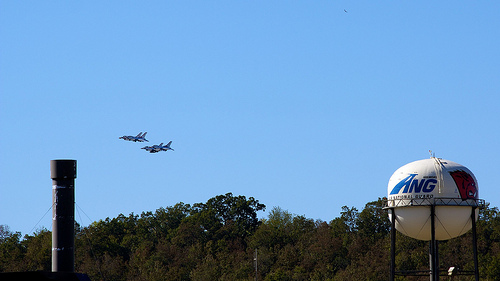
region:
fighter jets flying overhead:
[118, 115, 198, 169]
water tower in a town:
[394, 151, 464, 277]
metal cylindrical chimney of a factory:
[29, 146, 95, 279]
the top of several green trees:
[143, 206, 359, 271]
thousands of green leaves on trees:
[117, 225, 190, 267]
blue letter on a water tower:
[396, 174, 441, 200]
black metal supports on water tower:
[400, 238, 474, 279]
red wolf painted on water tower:
[446, 163, 479, 210]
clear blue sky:
[216, 38, 406, 125]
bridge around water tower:
[416, 196, 446, 202]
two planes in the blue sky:
[116, 130, 176, 157]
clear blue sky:
[1, 0, 499, 244]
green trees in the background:
[0, 189, 499, 278]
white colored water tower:
[381, 145, 485, 279]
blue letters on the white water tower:
[391, 172, 438, 196]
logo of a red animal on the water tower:
[446, 165, 478, 202]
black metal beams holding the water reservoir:
[380, 197, 485, 279]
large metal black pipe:
[48, 157, 80, 275]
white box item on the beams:
[445, 262, 458, 276]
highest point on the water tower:
[428, 148, 436, 163]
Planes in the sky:
[108, 120, 179, 161]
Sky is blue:
[0, 2, 495, 187]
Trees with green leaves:
[0, 181, 495, 276]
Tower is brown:
[40, 150, 82, 275]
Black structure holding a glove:
[374, 189, 494, 279]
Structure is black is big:
[372, 190, 493, 277]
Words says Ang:
[385, 167, 440, 194]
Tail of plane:
[135, 126, 146, 141]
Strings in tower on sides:
[21, 192, 99, 239]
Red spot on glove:
[443, 163, 484, 208]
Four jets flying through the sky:
[118, 133, 173, 153]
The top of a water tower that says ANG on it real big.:
[385, 147, 482, 239]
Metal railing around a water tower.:
[375, 196, 485, 211]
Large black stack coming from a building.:
[49, 157, 77, 274]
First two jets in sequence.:
[116, 129, 155, 144]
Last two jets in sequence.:
[141, 140, 173, 154]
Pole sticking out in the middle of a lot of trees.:
[252, 243, 259, 273]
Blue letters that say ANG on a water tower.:
[390, 172, 439, 195]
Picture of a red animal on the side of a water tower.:
[446, 170, 478, 201]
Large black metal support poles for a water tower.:
[385, 206, 482, 278]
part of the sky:
[318, 62, 424, 122]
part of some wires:
[69, 207, 106, 249]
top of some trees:
[211, 200, 262, 232]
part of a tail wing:
[159, 127, 180, 154]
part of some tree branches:
[258, 235, 295, 270]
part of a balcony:
[396, 183, 434, 205]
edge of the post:
[51, 159, 81, 189]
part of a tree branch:
[327, 177, 365, 234]